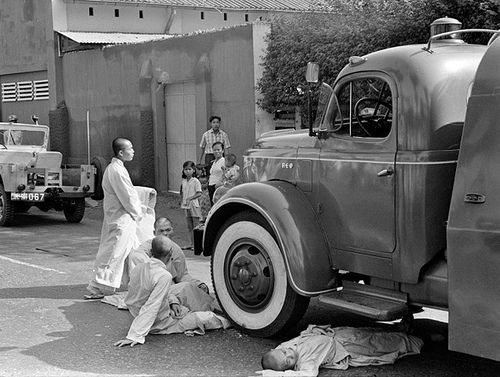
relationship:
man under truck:
[255, 318, 450, 376] [193, 8, 499, 372]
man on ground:
[112, 238, 236, 347] [1, 189, 498, 375]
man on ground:
[136, 215, 211, 298] [1, 189, 498, 375]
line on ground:
[2, 247, 71, 280] [1, 189, 498, 375]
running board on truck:
[315, 276, 412, 322] [193, 8, 499, 372]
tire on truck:
[204, 208, 308, 340] [193, 8, 499, 372]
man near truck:
[112, 238, 236, 347] [193, 8, 499, 372]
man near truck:
[136, 215, 211, 298] [193, 8, 499, 372]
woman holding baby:
[206, 138, 229, 206] [221, 151, 240, 194]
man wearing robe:
[80, 131, 160, 302] [86, 156, 156, 296]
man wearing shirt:
[198, 114, 238, 180] [199, 128, 234, 156]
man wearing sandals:
[80, 131, 160, 302] [85, 289, 106, 301]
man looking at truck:
[80, 131, 160, 302] [193, 8, 499, 372]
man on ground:
[255, 318, 450, 376] [1, 189, 498, 375]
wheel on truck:
[204, 208, 308, 340] [193, 8, 499, 372]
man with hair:
[198, 114, 238, 180] [207, 115, 222, 125]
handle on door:
[376, 166, 394, 180] [318, 65, 403, 257]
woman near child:
[206, 138, 229, 206] [176, 159, 206, 252]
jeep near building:
[0, 112, 101, 229] [1, 2, 367, 204]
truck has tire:
[193, 8, 499, 372] [204, 208, 308, 340]